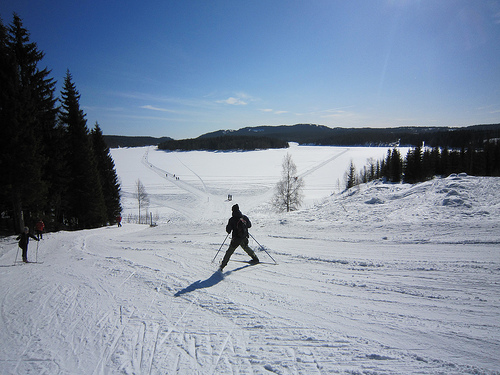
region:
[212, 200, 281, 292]
a skier in the center of the slope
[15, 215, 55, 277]
a skier in black at the edge of the slope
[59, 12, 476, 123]
a blue sky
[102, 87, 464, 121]
wispy clouds on the horizon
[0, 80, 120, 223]
a cluster of evergreen trees to the right of the ski slope on the way downhill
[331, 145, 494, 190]
a cluster of evergreen trees to the left of the ski slope on the way downhill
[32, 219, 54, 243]
a distant person in red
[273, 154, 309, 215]
a bare tree to the right of the slope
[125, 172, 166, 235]
a bare tree to the left of the slope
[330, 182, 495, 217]
a rough pile of snow on the right side of the slope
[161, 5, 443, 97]
this is the sky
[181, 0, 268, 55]
the sky is blue in color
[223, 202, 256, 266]
this is a man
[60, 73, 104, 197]
this is a tree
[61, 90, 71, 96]
the tree has green leaves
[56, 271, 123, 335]
this is a snow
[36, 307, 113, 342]
the snow is white in color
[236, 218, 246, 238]
this is a bag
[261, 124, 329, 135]
this is a mountain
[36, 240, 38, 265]
this is a stick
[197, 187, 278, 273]
Man on a snow field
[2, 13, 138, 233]
Green pine trees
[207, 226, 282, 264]
Two ski poles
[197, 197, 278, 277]
Man wearing snow skis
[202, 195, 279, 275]
Skier wearing a cap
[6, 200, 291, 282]
Two skiers with poles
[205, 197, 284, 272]
Skier wearing black jacket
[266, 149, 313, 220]
Tree without leaves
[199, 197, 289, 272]
Man wearing dark trousers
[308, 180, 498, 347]
Snow in ski track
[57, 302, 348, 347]
snow covering the ground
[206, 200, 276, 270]
skier moving on surface of snow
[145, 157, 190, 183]
people in distance moving on trail in snow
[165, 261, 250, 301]
dark shadow of skier on snow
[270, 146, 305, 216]
tree devoid of leaves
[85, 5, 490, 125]
blue sky with few clouds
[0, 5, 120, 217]
group of tall dark trees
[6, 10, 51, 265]
people near tall trees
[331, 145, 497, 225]
mound of loose snow near trees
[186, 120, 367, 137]
mountains in the distance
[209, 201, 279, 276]
a person skiing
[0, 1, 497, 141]
the sky is clear and blue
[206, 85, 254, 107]
a puffy white cloud in the sky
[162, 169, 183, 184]
a group of skiers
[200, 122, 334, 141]
a mountain in the distance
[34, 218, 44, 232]
a skier wearing a red jacket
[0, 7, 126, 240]
a group of evergreen trees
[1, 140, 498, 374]
the snow is white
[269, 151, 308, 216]
a tree without leaves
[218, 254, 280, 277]
a person wearing skis